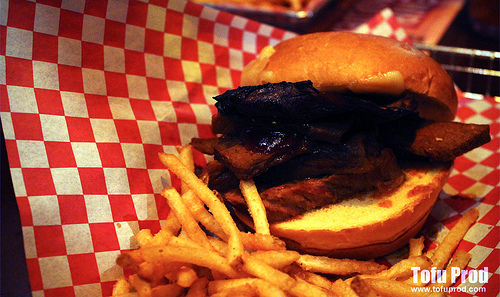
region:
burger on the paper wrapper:
[200, 29, 469, 279]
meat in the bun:
[184, 106, 480, 219]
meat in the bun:
[212, 89, 437, 185]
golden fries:
[166, 228, 231, 280]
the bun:
[342, 204, 382, 234]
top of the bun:
[323, 38, 361, 63]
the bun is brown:
[311, 43, 354, 65]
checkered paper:
[20, 97, 109, 194]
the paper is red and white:
[43, 71, 148, 196]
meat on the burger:
[243, 100, 357, 183]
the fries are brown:
[245, 260, 288, 289]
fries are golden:
[192, 227, 262, 289]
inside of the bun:
[325, 202, 354, 223]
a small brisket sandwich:
[201, 33, 491, 244]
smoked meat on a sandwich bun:
[208, 47, 489, 247]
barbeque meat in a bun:
[195, 34, 490, 268]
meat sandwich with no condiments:
[201, 35, 492, 255]